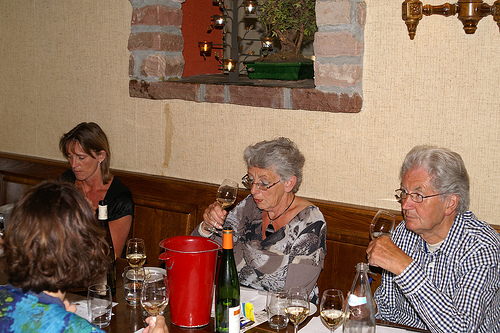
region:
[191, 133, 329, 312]
Woman drinking a glass of wine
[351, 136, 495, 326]
Gray haired man drinking a glass of wine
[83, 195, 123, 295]
Bottle of wine on the table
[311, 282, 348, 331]
Glass of wine sitting on the table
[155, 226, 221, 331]
Red bucket sitting on the table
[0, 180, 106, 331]
Woman in a green and blue shirt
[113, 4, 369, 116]
Brick framed hole in the wall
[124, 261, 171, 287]
Small white plate on the table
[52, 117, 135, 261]
Woman in a short sleeved black shirt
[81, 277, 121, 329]
Water glass on the table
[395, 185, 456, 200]
a man's eyeglasses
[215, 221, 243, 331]
a tall green wine bottle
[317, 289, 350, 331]
a wine glass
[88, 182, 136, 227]
part of a woman's short sleeve shirt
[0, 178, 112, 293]
a woman's brown hair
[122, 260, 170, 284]
a white plate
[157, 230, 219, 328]
a tall red bucket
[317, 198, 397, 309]
a wooden bench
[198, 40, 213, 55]
a tea light candle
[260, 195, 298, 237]
a woman's black necklace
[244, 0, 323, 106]
Bonsai tree in window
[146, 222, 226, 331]
Red ice bucket on table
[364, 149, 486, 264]
Older gentleman drinking wine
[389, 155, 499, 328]
Man in a black and white plaid shirt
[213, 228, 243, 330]
Green glass wine bottle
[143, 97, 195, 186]
Brown stain on wall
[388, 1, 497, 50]
Wooden light fixture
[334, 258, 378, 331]
Clear glass water bottle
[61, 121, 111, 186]
Woman wearing small earrings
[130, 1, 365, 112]
Red brick window frame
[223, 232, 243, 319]
a green wine bottle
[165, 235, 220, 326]
a red ice bucket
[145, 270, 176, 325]
a clear wine glass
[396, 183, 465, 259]
a man wearing glasses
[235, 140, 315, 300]
a woman with a black necklace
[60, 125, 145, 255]
a woman wearing black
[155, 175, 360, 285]
Sitting in a wooden booth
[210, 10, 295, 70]
small black colored candles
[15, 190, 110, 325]
a woman with brown hair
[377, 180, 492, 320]
a man wearing a blue, black, and white shirt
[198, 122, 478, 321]
man and woman holding wine glasses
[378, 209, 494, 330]
man's shirt is checkered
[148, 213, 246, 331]
the container is red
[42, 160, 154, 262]
woman's shirt is black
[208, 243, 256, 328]
the wine bottle is green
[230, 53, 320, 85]
the plant container is green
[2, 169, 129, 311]
woman's hair is brown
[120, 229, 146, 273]
brown liquid in glass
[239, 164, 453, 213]
man and woman wearing glasses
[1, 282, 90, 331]
woman's shirt is blue